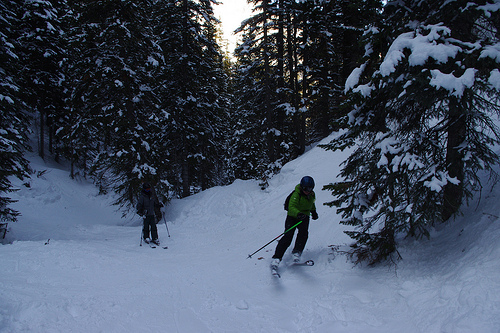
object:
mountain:
[1, 78, 496, 324]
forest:
[0, 2, 499, 256]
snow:
[38, 182, 313, 315]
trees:
[320, 0, 500, 265]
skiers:
[272, 176, 318, 266]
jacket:
[287, 184, 316, 217]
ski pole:
[162, 212, 170, 238]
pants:
[272, 216, 310, 262]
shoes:
[270, 257, 280, 268]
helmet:
[301, 175, 315, 192]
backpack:
[283, 190, 301, 211]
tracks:
[208, 284, 373, 315]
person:
[136, 183, 162, 240]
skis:
[147, 239, 168, 250]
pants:
[143, 215, 158, 239]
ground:
[0, 217, 497, 333]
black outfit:
[136, 193, 158, 217]